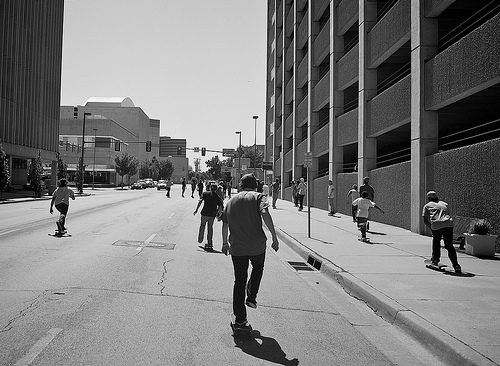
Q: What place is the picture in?
A: It is at the road.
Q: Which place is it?
A: It is a road.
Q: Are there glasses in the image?
A: No, there are no glasses.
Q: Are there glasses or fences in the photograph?
A: No, there are no glasses or fences.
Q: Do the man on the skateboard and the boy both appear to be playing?
A: Yes, both the man and the boy are playing.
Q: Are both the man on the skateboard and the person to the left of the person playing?
A: Yes, both the man and the boy are playing.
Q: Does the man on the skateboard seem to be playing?
A: Yes, the man is playing.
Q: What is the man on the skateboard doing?
A: The man is playing.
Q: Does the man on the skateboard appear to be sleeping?
A: No, the man is playing.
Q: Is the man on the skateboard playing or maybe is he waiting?
A: The man is playing.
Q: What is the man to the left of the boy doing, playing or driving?
A: The man is playing.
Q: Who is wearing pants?
A: The man is wearing pants.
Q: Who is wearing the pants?
A: The man is wearing pants.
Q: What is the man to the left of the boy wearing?
A: The man is wearing trousers.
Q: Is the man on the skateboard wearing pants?
A: Yes, the man is wearing pants.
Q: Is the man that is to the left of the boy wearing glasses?
A: No, the man is wearing pants.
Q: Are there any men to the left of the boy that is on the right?
A: Yes, there is a man to the left of the boy.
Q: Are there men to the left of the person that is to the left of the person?
A: Yes, there is a man to the left of the boy.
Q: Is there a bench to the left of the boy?
A: No, there is a man to the left of the boy.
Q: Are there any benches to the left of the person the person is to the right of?
A: No, there is a man to the left of the boy.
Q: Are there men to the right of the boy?
A: Yes, there is a man to the right of the boy.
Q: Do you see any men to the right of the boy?
A: Yes, there is a man to the right of the boy.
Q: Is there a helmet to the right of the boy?
A: No, there is a man to the right of the boy.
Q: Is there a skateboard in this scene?
A: Yes, there is a skateboard.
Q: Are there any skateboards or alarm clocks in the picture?
A: Yes, there is a skateboard.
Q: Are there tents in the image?
A: No, there are no tents.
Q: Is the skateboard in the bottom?
A: Yes, the skateboard is in the bottom of the image.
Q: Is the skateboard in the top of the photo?
A: No, the skateboard is in the bottom of the image.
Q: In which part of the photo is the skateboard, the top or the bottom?
A: The skateboard is in the bottom of the image.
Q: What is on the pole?
A: The sign is on the pole.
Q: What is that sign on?
A: The sign is on the pole.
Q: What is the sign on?
A: The sign is on the pole.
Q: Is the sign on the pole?
A: Yes, the sign is on the pole.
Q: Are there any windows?
A: Yes, there is a window.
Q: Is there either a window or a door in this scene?
A: Yes, there is a window.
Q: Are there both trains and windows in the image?
A: No, there is a window but no trains.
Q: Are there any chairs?
A: No, there are no chairs.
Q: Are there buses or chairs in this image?
A: No, there are no chairs or buses.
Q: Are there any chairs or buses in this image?
A: No, there are no chairs or buses.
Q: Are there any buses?
A: No, there are no buses.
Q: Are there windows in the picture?
A: Yes, there is a window.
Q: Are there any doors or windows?
A: Yes, there is a window.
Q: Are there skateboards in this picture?
A: Yes, there is a skateboard.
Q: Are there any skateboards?
A: Yes, there is a skateboard.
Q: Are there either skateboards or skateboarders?
A: Yes, there is a skateboard.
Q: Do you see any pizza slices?
A: No, there are no pizza slices.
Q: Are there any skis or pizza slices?
A: No, there are no pizza slices or skis.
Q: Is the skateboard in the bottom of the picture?
A: Yes, the skateboard is in the bottom of the image.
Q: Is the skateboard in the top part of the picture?
A: No, the skateboard is in the bottom of the image.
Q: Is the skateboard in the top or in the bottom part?
A: The skateboard is in the bottom of the image.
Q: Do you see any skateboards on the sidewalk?
A: Yes, there is a skateboard on the sidewalk.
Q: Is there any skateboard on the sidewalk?
A: Yes, there is a skateboard on the sidewalk.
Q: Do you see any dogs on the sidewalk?
A: No, there is a skateboard on the sidewalk.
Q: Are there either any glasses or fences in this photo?
A: No, there are no fences or glasses.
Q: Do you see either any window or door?
A: Yes, there is a window.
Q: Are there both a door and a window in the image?
A: No, there is a window but no doors.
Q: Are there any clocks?
A: No, there are no clocks.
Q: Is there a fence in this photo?
A: No, there are no fences.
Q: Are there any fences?
A: No, there are no fences.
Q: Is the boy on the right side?
A: Yes, the boy is on the right of the image.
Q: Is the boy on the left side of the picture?
A: No, the boy is on the right of the image.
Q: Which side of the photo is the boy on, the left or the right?
A: The boy is on the right of the image.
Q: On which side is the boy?
A: The boy is on the right of the image.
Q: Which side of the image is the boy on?
A: The boy is on the right of the image.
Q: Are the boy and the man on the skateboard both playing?
A: Yes, both the boy and the man are playing.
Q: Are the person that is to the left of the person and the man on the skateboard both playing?
A: Yes, both the boy and the man are playing.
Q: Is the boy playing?
A: Yes, the boy is playing.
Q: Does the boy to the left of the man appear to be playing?
A: Yes, the boy is playing.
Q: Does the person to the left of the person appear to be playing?
A: Yes, the boy is playing.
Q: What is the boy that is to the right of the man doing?
A: The boy is playing.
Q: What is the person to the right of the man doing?
A: The boy is playing.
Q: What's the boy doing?
A: The boy is playing.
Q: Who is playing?
A: The boy is playing.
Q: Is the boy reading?
A: No, the boy is playing.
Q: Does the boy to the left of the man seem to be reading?
A: No, the boy is playing.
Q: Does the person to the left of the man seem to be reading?
A: No, the boy is playing.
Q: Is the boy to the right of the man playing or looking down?
A: The boy is playing.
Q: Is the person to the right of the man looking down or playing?
A: The boy is playing.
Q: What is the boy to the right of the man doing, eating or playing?
A: The boy is playing.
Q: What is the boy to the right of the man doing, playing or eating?
A: The boy is playing.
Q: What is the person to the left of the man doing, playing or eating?
A: The boy is playing.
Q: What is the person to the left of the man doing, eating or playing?
A: The boy is playing.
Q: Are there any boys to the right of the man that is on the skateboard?
A: Yes, there is a boy to the right of the man.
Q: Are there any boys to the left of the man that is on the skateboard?
A: No, the boy is to the right of the man.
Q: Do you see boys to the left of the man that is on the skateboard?
A: No, the boy is to the right of the man.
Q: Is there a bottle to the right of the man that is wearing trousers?
A: No, there is a boy to the right of the man.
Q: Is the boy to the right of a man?
A: Yes, the boy is to the right of a man.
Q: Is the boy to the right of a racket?
A: No, the boy is to the right of a man.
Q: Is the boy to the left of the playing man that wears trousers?
A: No, the boy is to the right of the man.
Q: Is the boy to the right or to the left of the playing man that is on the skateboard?
A: The boy is to the right of the man.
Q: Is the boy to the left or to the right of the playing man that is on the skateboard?
A: The boy is to the right of the man.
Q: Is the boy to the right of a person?
A: No, the boy is to the left of a person.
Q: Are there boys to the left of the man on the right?
A: Yes, there is a boy to the left of the man.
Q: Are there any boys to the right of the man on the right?
A: No, the boy is to the left of the man.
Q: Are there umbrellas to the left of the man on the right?
A: No, there is a boy to the left of the man.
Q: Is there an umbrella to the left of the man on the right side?
A: No, there is a boy to the left of the man.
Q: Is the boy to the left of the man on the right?
A: Yes, the boy is to the left of the man.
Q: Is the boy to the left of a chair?
A: No, the boy is to the left of the man.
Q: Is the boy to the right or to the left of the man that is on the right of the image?
A: The boy is to the left of the man.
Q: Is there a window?
A: Yes, there is a window.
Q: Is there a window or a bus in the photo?
A: Yes, there is a window.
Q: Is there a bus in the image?
A: No, there are no buses.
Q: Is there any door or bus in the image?
A: No, there are no buses or doors.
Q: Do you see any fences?
A: No, there are no fences.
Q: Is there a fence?
A: No, there are no fences.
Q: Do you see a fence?
A: No, there are no fences.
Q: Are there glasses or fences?
A: No, there are no fences or glasses.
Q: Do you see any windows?
A: Yes, there is a window.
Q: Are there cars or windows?
A: Yes, there is a window.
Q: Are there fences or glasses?
A: No, there are no glasses or fences.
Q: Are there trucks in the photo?
A: No, there are no trucks.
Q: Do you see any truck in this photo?
A: No, there are no trucks.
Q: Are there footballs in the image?
A: No, there are no footballs.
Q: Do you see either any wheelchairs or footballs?
A: No, there are no footballs or wheelchairs.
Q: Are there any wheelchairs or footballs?
A: No, there are no footballs or wheelchairs.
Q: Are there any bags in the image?
A: No, there are no bags.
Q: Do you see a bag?
A: No, there are no bags.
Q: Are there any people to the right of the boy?
A: Yes, there is a person to the right of the boy.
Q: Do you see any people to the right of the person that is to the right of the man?
A: Yes, there is a person to the right of the boy.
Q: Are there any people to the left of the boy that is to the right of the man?
A: No, the person is to the right of the boy.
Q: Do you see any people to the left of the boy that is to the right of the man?
A: No, the person is to the right of the boy.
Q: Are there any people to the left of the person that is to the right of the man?
A: No, the person is to the right of the boy.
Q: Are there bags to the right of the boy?
A: No, there is a person to the right of the boy.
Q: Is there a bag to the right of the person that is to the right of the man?
A: No, there is a person to the right of the boy.